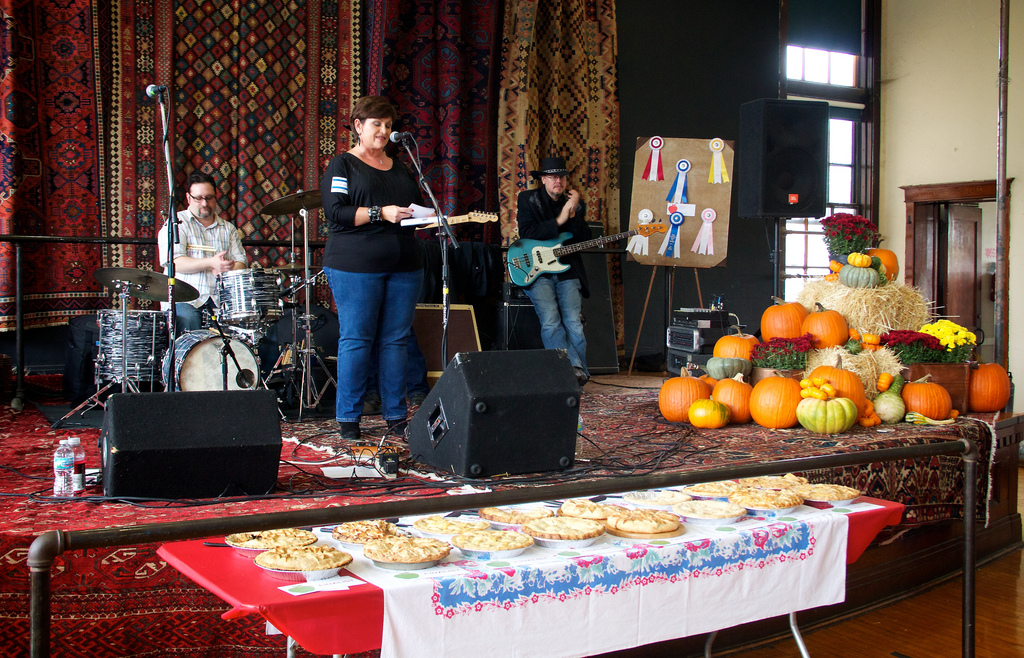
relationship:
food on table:
[195, 469, 907, 573] [146, 470, 921, 648]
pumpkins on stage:
[636, 214, 1008, 442] [10, 365, 1013, 496]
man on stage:
[131, 163, 272, 285] [10, 365, 1013, 496]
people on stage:
[321, 95, 441, 439] [10, 365, 1013, 496]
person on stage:
[505, 145, 621, 401] [10, 365, 1013, 496]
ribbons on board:
[648, 135, 725, 257] [623, 130, 742, 272]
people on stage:
[134, 110, 682, 451] [10, 365, 1013, 496]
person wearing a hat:
[505, 145, 621, 401] [527, 148, 582, 182]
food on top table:
[195, 469, 907, 573] [146, 470, 921, 648]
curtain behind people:
[9, 4, 650, 313] [134, 110, 682, 451]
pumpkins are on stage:
[636, 214, 1008, 442] [10, 365, 1013, 496]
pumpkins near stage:
[636, 214, 1008, 442] [10, 365, 1013, 496]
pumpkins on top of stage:
[636, 214, 1008, 442] [10, 365, 1013, 496]